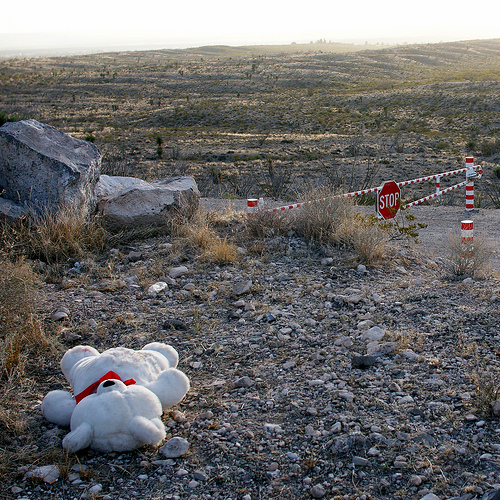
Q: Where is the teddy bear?
A: Lying on the ground.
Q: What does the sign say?
A: Stop.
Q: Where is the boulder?
A: Behind the bear, on the left.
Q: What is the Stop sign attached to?
A: A road barricade.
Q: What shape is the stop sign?
A: Octagonal.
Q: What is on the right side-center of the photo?
A: Two huge rocks.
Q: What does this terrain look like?
A: Rocky desert.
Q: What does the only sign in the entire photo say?
A: Stop.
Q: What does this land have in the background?
A: Hills.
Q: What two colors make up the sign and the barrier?
A: Red and white.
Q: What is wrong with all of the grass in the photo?
A: Dry and dead.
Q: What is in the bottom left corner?
A: Teddy bear.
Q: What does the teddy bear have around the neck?
A: Red ribbon.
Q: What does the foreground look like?
A: Rocky rocks.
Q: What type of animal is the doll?
A: Teddy bear.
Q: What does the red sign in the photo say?
A: Stop.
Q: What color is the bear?
A: White.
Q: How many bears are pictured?
A: One.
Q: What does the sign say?
A: Stop.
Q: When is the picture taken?
A: Daytime.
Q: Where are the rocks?
A: On the ground.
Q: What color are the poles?
A: Red and white.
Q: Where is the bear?
A: On the rocks.